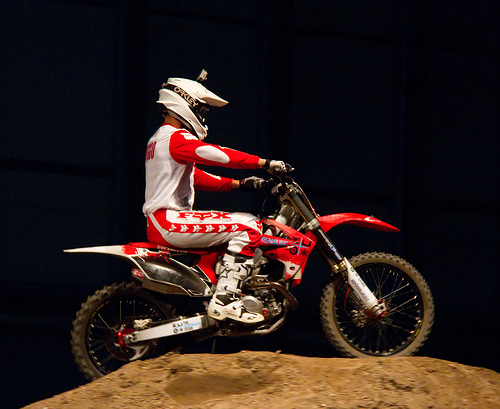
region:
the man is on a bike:
[65, 76, 430, 382]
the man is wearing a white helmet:
[158, 77, 225, 137]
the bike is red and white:
[63, 213, 433, 380]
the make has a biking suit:
[147, 126, 284, 259]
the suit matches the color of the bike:
[68, 74, 430, 369]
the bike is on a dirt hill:
[74, 75, 430, 376]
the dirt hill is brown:
[21, 350, 498, 406]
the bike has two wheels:
[73, 250, 435, 381]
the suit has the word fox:
[176, 210, 232, 218]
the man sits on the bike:
[66, 77, 431, 386]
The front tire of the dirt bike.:
[315, 256, 432, 356]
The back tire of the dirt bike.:
[75, 290, 177, 367]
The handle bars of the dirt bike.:
[247, 163, 291, 198]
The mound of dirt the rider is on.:
[19, 328, 498, 403]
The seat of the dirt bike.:
[132, 233, 206, 260]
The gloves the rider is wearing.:
[245, 152, 282, 187]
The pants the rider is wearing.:
[147, 210, 264, 257]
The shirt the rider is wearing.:
[152, 126, 256, 210]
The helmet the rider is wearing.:
[160, 78, 225, 140]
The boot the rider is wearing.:
[198, 251, 267, 322]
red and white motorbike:
[65, 175, 432, 370]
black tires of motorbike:
[53, 249, 436, 357]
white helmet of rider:
[158, 74, 237, 141]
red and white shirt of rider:
[137, 130, 269, 204]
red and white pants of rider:
[148, 212, 258, 250]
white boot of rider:
[198, 270, 263, 319]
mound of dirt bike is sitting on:
[46, 340, 495, 407]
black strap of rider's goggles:
[158, 82, 200, 116]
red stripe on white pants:
[153, 211, 255, 249]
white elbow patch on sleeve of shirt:
[196, 143, 226, 161]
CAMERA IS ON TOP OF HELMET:
[194, 68, 211, 83]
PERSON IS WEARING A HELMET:
[149, 63, 239, 140]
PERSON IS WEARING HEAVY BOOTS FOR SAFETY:
[200, 249, 291, 339]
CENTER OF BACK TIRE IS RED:
[101, 322, 153, 354]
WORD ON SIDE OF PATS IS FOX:
[167, 202, 273, 225]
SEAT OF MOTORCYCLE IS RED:
[128, 237, 248, 254]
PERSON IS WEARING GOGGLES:
[165, 80, 215, 117]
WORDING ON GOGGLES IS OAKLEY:
[162, 78, 204, 108]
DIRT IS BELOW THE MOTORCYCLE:
[28, 365, 497, 400]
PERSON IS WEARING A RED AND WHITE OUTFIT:
[141, 128, 264, 281]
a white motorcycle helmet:
[153, 74, 227, 140]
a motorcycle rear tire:
[71, 280, 193, 382]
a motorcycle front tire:
[319, 252, 435, 361]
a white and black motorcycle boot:
[205, 250, 264, 324]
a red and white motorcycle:
[61, 158, 436, 384]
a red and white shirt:
[143, 123, 284, 213]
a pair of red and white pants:
[145, 209, 263, 257]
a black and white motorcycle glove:
[264, 158, 288, 171]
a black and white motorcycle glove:
[246, 175, 263, 187]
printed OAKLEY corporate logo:
[173, 83, 196, 106]